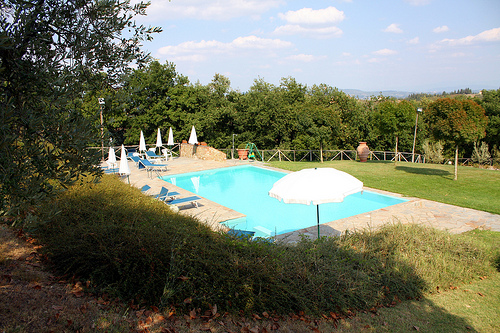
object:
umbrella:
[267, 166, 365, 239]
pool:
[159, 159, 406, 237]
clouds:
[124, 0, 500, 95]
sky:
[115, 0, 499, 93]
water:
[154, 164, 408, 242]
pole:
[316, 205, 320, 241]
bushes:
[0, 152, 500, 332]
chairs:
[138, 158, 168, 172]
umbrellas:
[187, 126, 198, 159]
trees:
[428, 95, 489, 166]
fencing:
[88, 142, 499, 165]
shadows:
[395, 166, 453, 181]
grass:
[263, 159, 498, 220]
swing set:
[239, 142, 264, 164]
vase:
[356, 141, 371, 162]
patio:
[110, 154, 499, 252]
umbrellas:
[119, 143, 131, 183]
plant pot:
[236, 149, 250, 160]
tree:
[3, 1, 162, 232]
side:
[1, 2, 201, 333]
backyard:
[6, 144, 496, 332]